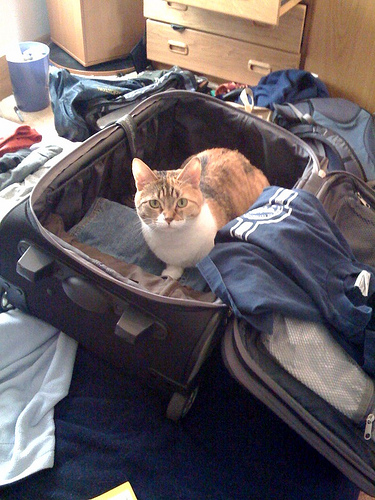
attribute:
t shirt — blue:
[214, 198, 353, 315]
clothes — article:
[162, 21, 190, 34]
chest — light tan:
[143, 0, 306, 91]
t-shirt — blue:
[189, 185, 373, 380]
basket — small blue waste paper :
[4, 40, 51, 111]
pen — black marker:
[14, 105, 26, 123]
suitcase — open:
[8, 87, 349, 425]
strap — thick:
[277, 112, 371, 182]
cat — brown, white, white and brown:
[127, 145, 277, 281]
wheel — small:
[167, 385, 201, 425]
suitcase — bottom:
[32, 91, 361, 459]